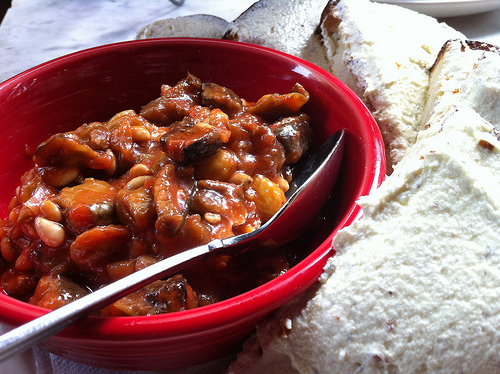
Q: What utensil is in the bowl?
A: A spoon.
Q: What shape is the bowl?
A: Round.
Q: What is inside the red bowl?
A: The silver spoon.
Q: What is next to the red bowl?
A: Slices of bread.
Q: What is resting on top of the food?
A: The silver spoon.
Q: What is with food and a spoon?
A: The red bowl.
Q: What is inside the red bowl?
A: Red and white beans.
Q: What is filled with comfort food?
A: The bowl.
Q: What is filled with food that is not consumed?
A: The bowl.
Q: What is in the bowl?
A: The spoon.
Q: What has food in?
A: The red bowl.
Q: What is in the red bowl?
A: Food.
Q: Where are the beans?
A: In bowl.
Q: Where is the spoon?
A: In bowl.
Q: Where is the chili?
A: In bowl.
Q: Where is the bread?
A: Right side.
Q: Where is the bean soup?
A: In bowl.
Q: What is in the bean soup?
A: Spoon.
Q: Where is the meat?
A: In chili.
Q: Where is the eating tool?
A: In bowl.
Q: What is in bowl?
A: Beef stew.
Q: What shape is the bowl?
A: Circle.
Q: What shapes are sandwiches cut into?
A: Triangles.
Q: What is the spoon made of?
A: Metal.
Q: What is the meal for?
A: Lunch.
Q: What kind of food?
A: Chili.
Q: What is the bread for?
A: Dipping.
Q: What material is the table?
A: Metal.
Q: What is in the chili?
A: Vegetables.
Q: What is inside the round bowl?
A: Food.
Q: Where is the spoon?
A: In the bowl.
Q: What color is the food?
A: Brown.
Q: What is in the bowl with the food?
A: A spoon.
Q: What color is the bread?
A: White.